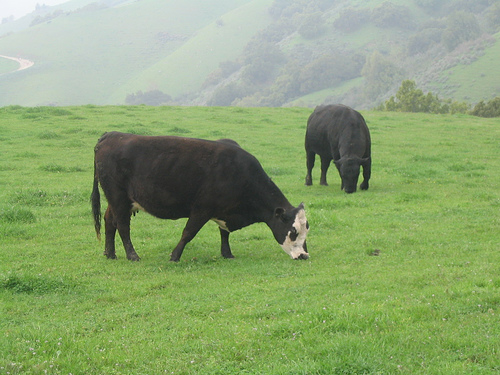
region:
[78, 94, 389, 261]
Cows in the feild.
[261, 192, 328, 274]
A cow eats grass.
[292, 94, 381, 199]
The other cow eats.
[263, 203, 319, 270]
The face is white.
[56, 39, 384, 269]
The cows are black.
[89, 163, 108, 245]
The tail of the cow.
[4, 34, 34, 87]
A winding road in the distance.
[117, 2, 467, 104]
Trees on the hillside.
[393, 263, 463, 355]
Small flowers in the field.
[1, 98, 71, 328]
Overgrown patches of grass.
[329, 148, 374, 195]
Cow's head is black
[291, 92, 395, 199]
Black cow eating grass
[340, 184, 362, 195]
Cow's nose is black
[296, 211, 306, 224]
White patch on cow's head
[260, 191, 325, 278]
Cow's head is white and black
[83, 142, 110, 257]
Black tail on cow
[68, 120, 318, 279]
Black and white cow eating grass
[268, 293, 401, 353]
Green grass in field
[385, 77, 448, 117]
Green bushes behind grass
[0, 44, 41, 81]
Pale white open highway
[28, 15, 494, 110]
The fog is light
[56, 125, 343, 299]
The cow is eating.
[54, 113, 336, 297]
The cow is black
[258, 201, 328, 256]
The cow has a white face.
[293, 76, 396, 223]
The cow is all black.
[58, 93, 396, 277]
Two cows standing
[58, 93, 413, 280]
two cows eating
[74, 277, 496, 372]
The grass is lush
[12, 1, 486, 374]
The hills are large.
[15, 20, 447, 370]
They are in a field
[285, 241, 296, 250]
THE COW IS BLACK AND WHITE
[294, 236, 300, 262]
THE COW IS BLACK AND WHITE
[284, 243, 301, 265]
THE COW IS BLACK AND WHITE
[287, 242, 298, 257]
THE COW IS BLACK AND WHITE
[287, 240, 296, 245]
THE COW IS BLACK AND WHITE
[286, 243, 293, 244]
THE COW IS BLACK AND WHITE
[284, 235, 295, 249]
THE COW IS BLACK AND WHITE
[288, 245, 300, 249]
THE COW IS BLACK AND WHITE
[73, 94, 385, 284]
two cows in the meadow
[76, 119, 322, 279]
a white and black cow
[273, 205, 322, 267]
face of cow is white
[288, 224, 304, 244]
eye of cow has a black spot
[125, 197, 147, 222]
udders of cow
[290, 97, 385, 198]
a black cow eating grass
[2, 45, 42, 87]
a road in the hill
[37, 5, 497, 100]
mountain is covered with green grass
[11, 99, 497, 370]
field is cover with grass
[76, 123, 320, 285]
cow is eating grass